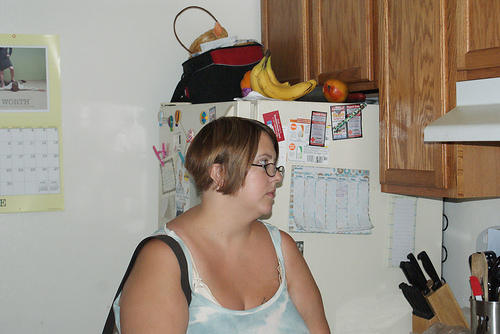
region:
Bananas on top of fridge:
[235, 44, 317, 102]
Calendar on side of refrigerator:
[287, 162, 383, 235]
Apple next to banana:
[307, 68, 354, 103]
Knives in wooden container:
[401, 242, 464, 333]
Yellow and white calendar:
[0, 23, 75, 218]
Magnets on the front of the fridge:
[146, 108, 193, 198]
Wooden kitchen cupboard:
[371, 4, 461, 194]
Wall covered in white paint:
[4, 0, 176, 327]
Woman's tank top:
[143, 222, 333, 333]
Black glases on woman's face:
[253, 149, 290, 181]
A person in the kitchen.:
[124, 80, 485, 332]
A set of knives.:
[390, 247, 471, 332]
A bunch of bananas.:
[249, 49, 323, 101]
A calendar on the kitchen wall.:
[2, 31, 69, 228]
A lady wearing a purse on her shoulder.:
[100, 113, 339, 331]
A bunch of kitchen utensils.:
[460, 240, 498, 331]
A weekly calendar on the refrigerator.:
[282, 166, 380, 244]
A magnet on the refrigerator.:
[262, 106, 294, 142]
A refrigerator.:
[153, 94, 448, 331]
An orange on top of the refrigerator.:
[317, 73, 351, 115]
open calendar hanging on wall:
[1, 0, 258, 330]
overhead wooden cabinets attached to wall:
[256, 1, 496, 191]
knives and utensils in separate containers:
[400, 200, 495, 330]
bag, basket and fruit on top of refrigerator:
[165, 1, 350, 98]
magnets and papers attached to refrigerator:
[156, 105, 432, 330]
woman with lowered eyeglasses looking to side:
[180, 112, 285, 217]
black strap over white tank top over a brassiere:
[100, 211, 310, 326]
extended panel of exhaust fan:
[420, 71, 495, 141]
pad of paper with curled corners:
[285, 160, 375, 236]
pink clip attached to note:
[150, 136, 180, 196]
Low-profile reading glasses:
[250, 160, 285, 179]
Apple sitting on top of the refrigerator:
[324, 80, 348, 105]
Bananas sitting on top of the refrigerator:
[252, 50, 317, 100]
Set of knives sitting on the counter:
[398, 250, 468, 332]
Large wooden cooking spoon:
[469, 252, 489, 297]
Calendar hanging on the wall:
[0, 30, 64, 213]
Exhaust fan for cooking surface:
[421, 75, 498, 145]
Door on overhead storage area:
[375, 0, 456, 192]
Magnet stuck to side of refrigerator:
[263, 108, 283, 141]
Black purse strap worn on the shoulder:
[102, 232, 192, 332]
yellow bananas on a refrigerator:
[245, 50, 313, 103]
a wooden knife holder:
[396, 251, 466, 328]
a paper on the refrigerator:
[285, 166, 375, 241]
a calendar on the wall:
[4, 28, 62, 221]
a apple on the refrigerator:
[317, 75, 349, 111]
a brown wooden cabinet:
[377, 4, 456, 188]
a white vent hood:
[422, 79, 499, 144]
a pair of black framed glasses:
[240, 156, 285, 178]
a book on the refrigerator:
[178, 43, 263, 83]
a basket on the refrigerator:
[170, 2, 230, 51]